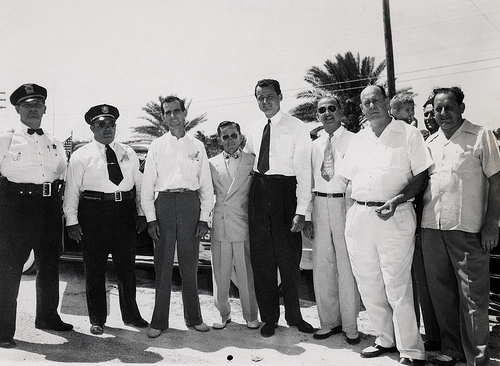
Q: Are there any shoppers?
A: No, there are no shoppers.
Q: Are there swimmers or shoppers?
A: No, there are no shoppers or swimmers.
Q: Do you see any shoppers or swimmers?
A: No, there are no shoppers or swimmers.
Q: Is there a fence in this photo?
A: No, there are no fences.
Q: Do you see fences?
A: No, there are no fences.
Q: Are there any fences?
A: No, there are no fences.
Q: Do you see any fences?
A: No, there are no fences.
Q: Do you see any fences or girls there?
A: No, there are no fences or girls.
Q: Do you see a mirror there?
A: No, there are no mirrors.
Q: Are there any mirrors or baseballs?
A: No, there are no mirrors or baseballs.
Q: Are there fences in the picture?
A: No, there are no fences.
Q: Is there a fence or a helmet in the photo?
A: No, there are no fences or helmets.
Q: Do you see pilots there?
A: No, there are no pilots.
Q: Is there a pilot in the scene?
A: No, there are no pilots.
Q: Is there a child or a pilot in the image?
A: No, there are no pilots or children.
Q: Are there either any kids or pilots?
A: No, there are no pilots or kids.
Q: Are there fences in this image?
A: No, there are no fences.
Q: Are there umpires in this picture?
A: No, there are no umpires.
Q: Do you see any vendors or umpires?
A: No, there are no umpires or vendors.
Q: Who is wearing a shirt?
A: The man is wearing a shirt.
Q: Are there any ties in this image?
A: Yes, there is a tie.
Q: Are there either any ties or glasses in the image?
A: Yes, there is a tie.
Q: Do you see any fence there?
A: No, there are no fences.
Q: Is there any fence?
A: No, there are no fences.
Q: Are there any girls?
A: No, there are no girls.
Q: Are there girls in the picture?
A: No, there are no girls.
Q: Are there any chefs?
A: No, there are no chefs.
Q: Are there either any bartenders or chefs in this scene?
A: No, there are no chefs or bartenders.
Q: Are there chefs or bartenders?
A: No, there are no chefs or bartenders.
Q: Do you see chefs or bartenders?
A: No, there are no chefs or bartenders.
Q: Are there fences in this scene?
A: No, there are no fences.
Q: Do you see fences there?
A: No, there are no fences.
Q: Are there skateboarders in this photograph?
A: No, there are no skateboarders.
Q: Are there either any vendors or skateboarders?
A: No, there are no skateboarders or vendors.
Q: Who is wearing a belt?
A: The man is wearing a belt.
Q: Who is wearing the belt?
A: The man is wearing a belt.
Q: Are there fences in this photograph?
A: No, there are no fences.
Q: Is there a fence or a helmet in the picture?
A: No, there are no fences or helmets.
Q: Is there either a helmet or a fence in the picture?
A: No, there are no fences or helmets.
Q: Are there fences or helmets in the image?
A: No, there are no fences or helmets.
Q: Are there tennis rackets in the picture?
A: No, there are no tennis rackets.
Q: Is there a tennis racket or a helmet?
A: No, there are no rackets or helmets.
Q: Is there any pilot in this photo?
A: No, there are no pilots.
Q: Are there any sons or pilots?
A: No, there are no pilots or sons.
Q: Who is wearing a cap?
A: The man is wearing a cap.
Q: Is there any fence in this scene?
A: No, there are no fences.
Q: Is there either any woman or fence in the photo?
A: No, there are no fences or women.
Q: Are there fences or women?
A: No, there are no fences or women.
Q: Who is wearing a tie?
A: The man is wearing a tie.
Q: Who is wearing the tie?
A: The man is wearing a tie.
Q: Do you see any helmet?
A: No, there are no helmets.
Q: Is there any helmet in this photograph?
A: No, there are no helmets.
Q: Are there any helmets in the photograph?
A: No, there are no helmets.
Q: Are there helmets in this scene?
A: No, there are no helmets.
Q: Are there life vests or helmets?
A: No, there are no helmets or life vests.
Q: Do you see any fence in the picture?
A: No, there are no fences.